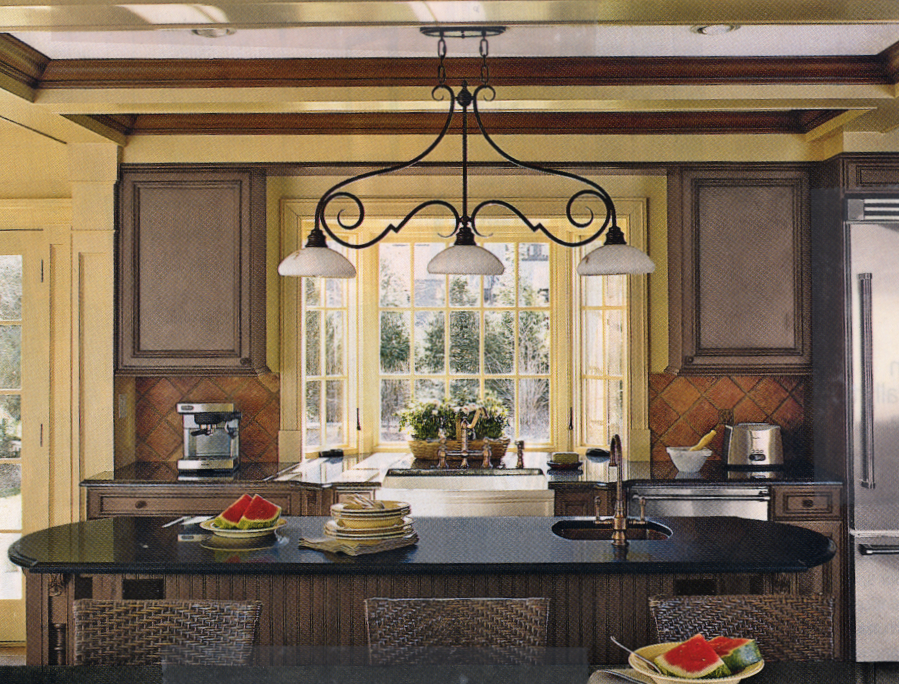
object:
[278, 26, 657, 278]
light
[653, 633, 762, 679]
watermelon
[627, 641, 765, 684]
bowl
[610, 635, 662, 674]
spoon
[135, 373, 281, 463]
backsplash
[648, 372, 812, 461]
backsplash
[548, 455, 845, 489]
counter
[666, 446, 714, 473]
bowl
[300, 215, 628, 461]
window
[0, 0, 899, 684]
kitchen